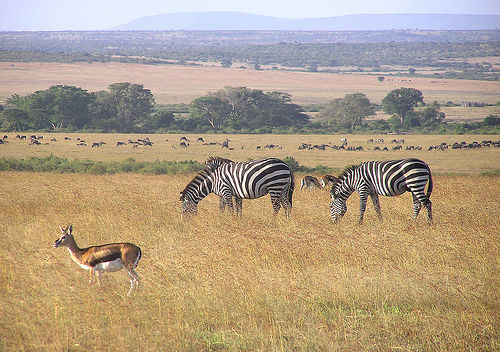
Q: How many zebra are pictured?
A: Two.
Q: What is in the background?
A: Trees.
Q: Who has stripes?
A: The zebra.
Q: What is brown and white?
A: Gazelle.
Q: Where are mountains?
A: In the distance.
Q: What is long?
A: The grass.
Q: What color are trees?
A: Green.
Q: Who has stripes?
A: The zebra.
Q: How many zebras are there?
A: Two.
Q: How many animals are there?
A: More than five.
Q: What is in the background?
A: Trees.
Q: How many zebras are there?
A: Two.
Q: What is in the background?
A: Trees.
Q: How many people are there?
A: None.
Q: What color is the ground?
A: Brown and green.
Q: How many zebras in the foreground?
A: Two.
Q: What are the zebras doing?
A: Eating grass.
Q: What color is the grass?
A: Tan.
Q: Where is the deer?
A: To the left of the zebras.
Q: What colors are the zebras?
A: Black and white.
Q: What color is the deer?
A: Brown.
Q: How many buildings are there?
A: None.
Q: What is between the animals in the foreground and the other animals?
A: Bushes.